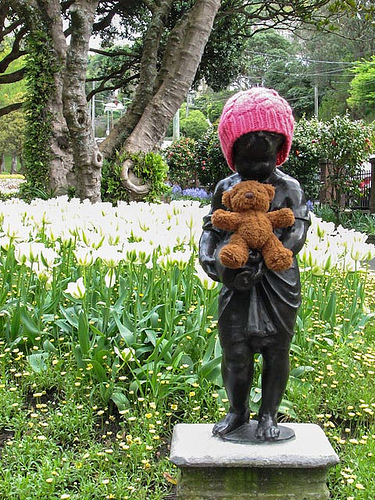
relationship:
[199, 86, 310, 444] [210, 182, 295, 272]
statue holding teddy bear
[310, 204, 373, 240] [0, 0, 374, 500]
hedge along garden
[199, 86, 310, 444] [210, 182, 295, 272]
statue holding stuffed animal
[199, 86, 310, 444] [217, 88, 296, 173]
statue wearing beanie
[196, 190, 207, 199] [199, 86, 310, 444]
flower behind statue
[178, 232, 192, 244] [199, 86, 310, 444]
flower behind statue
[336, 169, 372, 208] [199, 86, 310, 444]
fence behind statue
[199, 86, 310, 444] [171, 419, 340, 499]
statue on stone pedestal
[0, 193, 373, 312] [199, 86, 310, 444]
flower patch behind statue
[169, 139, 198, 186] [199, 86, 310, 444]
bush behind statue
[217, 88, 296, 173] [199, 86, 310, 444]
hat on statue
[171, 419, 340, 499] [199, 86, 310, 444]
stone structure holding statue